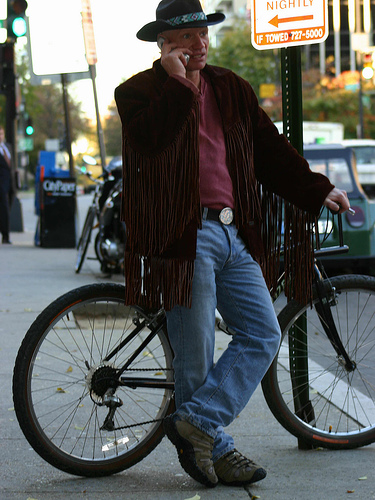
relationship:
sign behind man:
[251, 0, 329, 50] [114, 1, 350, 488]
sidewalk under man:
[0, 189, 375, 499] [114, 1, 350, 488]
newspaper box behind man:
[40, 175, 78, 247] [114, 1, 350, 488]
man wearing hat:
[114, 1, 350, 488] [137, 0, 225, 41]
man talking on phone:
[114, 1, 350, 488] [156, 38, 190, 63]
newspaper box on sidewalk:
[40, 175, 78, 247] [0, 189, 375, 499]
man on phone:
[114, 1, 350, 488] [156, 38, 190, 63]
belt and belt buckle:
[199, 207, 238, 224] [219, 207, 234, 224]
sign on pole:
[251, 0, 329, 50] [277, 46, 312, 448]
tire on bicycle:
[12, 284, 175, 477] [12, 202, 374, 477]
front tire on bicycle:
[261, 273, 374, 450] [12, 202, 374, 477]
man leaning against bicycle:
[114, 1, 350, 488] [12, 202, 374, 477]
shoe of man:
[165, 415, 218, 485] [114, 1, 350, 488]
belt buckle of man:
[219, 207, 234, 224] [114, 1, 350, 488]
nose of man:
[193, 32, 206, 51] [114, 1, 350, 488]